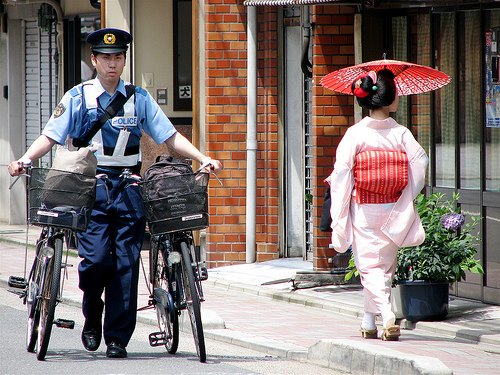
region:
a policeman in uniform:
[45, 73, 205, 300]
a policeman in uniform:
[149, 158, 274, 370]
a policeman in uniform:
[80, 139, 230, 351]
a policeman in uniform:
[52, 11, 157, 247]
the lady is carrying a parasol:
[321, 57, 492, 357]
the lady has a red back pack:
[337, 132, 428, 214]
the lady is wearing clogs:
[360, 315, 413, 345]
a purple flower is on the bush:
[423, 202, 470, 249]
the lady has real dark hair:
[349, 72, 419, 123]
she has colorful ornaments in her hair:
[340, 69, 387, 103]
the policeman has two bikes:
[3, 22, 243, 366]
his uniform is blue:
[21, 10, 228, 372]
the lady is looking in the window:
[339, 58, 476, 364]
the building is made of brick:
[213, 12, 276, 117]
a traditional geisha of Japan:
[320, 49, 452, 343]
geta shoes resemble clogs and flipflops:
[351, 317, 404, 352]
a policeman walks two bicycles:
[6, 20, 202, 354]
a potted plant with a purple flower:
[386, 173, 488, 328]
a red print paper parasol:
[318, 53, 449, 99]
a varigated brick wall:
[201, 7, 242, 263]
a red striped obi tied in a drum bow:
[345, 135, 415, 205]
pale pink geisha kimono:
[331, 111, 429, 307]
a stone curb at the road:
[210, 335, 461, 372]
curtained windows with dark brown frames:
[398, 14, 495, 200]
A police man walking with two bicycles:
[7, 26, 229, 363]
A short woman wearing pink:
[315, 56, 452, 344]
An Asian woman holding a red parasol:
[314, 60, 450, 342]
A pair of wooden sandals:
[352, 311, 407, 347]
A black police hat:
[86, 26, 136, 56]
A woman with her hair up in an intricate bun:
[350, 67, 404, 112]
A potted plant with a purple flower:
[398, 186, 480, 321]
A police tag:
[112, 115, 142, 130]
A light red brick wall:
[201, 2, 296, 261]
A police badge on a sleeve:
[45, 101, 71, 120]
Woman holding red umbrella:
[327, 67, 431, 339]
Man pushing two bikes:
[5, 49, 225, 364]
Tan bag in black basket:
[38, 130, 103, 202]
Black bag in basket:
[141, 146, 201, 221]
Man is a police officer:
[7, 52, 225, 359]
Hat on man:
[84, 20, 136, 55]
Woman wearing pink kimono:
[317, 66, 433, 341]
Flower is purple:
[438, 210, 467, 229]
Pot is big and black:
[396, 275, 456, 316]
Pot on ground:
[398, 270, 454, 320]